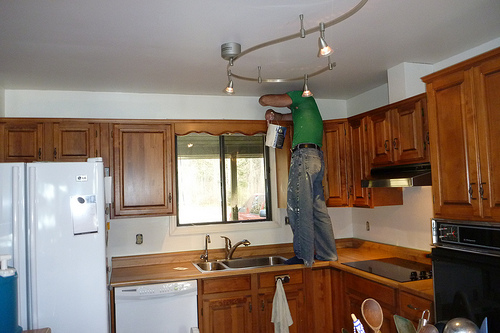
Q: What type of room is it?
A: It is a kitchen.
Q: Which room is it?
A: It is a kitchen.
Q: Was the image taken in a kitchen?
A: Yes, it was taken in a kitchen.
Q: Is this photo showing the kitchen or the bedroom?
A: It is showing the kitchen.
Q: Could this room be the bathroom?
A: No, it is the kitchen.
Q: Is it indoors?
A: Yes, it is indoors.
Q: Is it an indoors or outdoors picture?
A: It is indoors.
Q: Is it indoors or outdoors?
A: It is indoors.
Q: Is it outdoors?
A: No, it is indoors.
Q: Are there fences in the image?
A: No, there are no fences.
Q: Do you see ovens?
A: Yes, there is an oven.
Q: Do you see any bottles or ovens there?
A: Yes, there is an oven.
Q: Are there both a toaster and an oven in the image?
A: No, there is an oven but no toasters.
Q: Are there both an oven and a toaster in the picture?
A: No, there is an oven but no toasters.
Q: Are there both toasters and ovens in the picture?
A: No, there is an oven but no toasters.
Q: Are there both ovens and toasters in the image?
A: No, there is an oven but no toasters.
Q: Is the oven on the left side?
A: No, the oven is on the right of the image.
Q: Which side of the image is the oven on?
A: The oven is on the right of the image.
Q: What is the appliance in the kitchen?
A: The appliance is an oven.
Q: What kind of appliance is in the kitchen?
A: The appliance is an oven.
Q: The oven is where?
A: The oven is in the kitchen.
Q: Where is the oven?
A: The oven is in the kitchen.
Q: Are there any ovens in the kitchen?
A: Yes, there is an oven in the kitchen.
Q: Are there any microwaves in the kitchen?
A: No, there is an oven in the kitchen.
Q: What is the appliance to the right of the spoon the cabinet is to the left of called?
A: The appliance is an oven.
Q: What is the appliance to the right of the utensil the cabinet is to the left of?
A: The appliance is an oven.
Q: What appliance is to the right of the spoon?
A: The appliance is an oven.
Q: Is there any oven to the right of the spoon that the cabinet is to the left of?
A: Yes, there is an oven to the right of the spoon.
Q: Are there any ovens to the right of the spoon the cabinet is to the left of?
A: Yes, there is an oven to the right of the spoon.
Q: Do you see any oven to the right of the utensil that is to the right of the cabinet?
A: Yes, there is an oven to the right of the spoon.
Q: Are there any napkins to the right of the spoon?
A: No, there is an oven to the right of the spoon.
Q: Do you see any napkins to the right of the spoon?
A: No, there is an oven to the right of the spoon.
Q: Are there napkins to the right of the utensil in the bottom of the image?
A: No, there is an oven to the right of the spoon.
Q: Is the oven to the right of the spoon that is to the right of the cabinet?
A: Yes, the oven is to the right of the spoon.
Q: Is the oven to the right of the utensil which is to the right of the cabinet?
A: Yes, the oven is to the right of the spoon.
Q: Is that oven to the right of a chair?
A: No, the oven is to the right of the spoon.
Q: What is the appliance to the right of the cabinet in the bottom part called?
A: The appliance is an oven.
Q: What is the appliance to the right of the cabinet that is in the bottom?
A: The appliance is an oven.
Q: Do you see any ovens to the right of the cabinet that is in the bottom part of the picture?
A: Yes, there is an oven to the right of the cabinet.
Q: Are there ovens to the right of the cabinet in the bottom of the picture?
A: Yes, there is an oven to the right of the cabinet.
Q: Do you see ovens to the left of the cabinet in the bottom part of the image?
A: No, the oven is to the right of the cabinet.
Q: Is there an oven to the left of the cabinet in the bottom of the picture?
A: No, the oven is to the right of the cabinet.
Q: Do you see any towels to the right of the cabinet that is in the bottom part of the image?
A: No, there is an oven to the right of the cabinet.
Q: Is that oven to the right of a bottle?
A: No, the oven is to the right of the cabinet.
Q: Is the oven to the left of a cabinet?
A: No, the oven is to the right of a cabinet.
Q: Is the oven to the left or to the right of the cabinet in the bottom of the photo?
A: The oven is to the right of the cabinet.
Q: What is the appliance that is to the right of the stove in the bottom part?
A: The appliance is an oven.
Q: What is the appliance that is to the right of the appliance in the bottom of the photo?
A: The appliance is an oven.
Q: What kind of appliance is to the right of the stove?
A: The appliance is an oven.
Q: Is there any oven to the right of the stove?
A: Yes, there is an oven to the right of the stove.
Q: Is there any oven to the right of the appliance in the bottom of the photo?
A: Yes, there is an oven to the right of the stove.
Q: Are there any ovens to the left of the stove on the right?
A: No, the oven is to the right of the stove.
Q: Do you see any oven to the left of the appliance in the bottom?
A: No, the oven is to the right of the stove.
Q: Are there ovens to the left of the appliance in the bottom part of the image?
A: No, the oven is to the right of the stove.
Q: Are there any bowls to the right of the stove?
A: No, there is an oven to the right of the stove.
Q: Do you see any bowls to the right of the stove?
A: No, there is an oven to the right of the stove.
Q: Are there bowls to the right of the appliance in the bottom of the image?
A: No, there is an oven to the right of the stove.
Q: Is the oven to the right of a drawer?
A: No, the oven is to the right of the stove.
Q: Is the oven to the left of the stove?
A: No, the oven is to the right of the stove.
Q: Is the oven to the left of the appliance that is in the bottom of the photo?
A: No, the oven is to the right of the stove.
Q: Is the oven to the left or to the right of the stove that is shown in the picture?
A: The oven is to the right of the stove.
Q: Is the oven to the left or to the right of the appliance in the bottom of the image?
A: The oven is to the right of the stove.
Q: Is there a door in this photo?
A: Yes, there is a door.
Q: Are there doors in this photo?
A: Yes, there is a door.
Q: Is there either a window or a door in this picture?
A: Yes, there is a door.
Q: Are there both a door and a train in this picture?
A: No, there is a door but no trains.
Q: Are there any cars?
A: No, there are no cars.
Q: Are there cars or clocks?
A: No, there are no cars or clocks.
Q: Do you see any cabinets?
A: Yes, there is a cabinet.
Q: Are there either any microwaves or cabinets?
A: Yes, there is a cabinet.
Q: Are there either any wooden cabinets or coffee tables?
A: Yes, there is a wood cabinet.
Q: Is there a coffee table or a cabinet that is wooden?
A: Yes, the cabinet is wooden.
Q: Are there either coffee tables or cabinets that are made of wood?
A: Yes, the cabinet is made of wood.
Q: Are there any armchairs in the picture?
A: No, there are no armchairs.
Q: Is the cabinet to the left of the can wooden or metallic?
A: The cabinet is wooden.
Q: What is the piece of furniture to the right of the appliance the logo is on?
A: The piece of furniture is a cabinet.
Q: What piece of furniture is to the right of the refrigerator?
A: The piece of furniture is a cabinet.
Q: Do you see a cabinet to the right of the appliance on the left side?
A: Yes, there is a cabinet to the right of the freezer.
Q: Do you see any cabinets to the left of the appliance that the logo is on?
A: No, the cabinet is to the right of the refrigerator.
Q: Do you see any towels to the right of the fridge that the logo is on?
A: No, there is a cabinet to the right of the refrigerator.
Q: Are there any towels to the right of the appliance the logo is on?
A: No, there is a cabinet to the right of the refrigerator.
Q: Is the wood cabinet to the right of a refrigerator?
A: Yes, the cabinet is to the right of a refrigerator.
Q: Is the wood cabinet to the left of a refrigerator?
A: No, the cabinet is to the right of a refrigerator.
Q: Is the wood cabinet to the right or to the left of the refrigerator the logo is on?
A: The cabinet is to the right of the freezer.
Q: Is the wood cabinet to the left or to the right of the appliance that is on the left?
A: The cabinet is to the right of the freezer.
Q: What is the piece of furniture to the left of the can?
A: The piece of furniture is a cabinet.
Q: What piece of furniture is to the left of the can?
A: The piece of furniture is a cabinet.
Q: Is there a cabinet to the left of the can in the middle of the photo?
A: Yes, there is a cabinet to the left of the can.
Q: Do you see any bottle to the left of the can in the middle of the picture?
A: No, there is a cabinet to the left of the can.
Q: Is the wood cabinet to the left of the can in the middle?
A: Yes, the cabinet is to the left of the can.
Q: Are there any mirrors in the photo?
A: No, there are no mirrors.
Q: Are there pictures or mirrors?
A: No, there are no mirrors or pictures.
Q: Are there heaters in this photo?
A: No, there are no heaters.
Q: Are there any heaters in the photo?
A: No, there are no heaters.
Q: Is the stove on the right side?
A: Yes, the stove is on the right of the image.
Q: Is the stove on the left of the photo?
A: No, the stove is on the right of the image.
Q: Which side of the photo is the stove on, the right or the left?
A: The stove is on the right of the image.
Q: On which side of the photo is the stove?
A: The stove is on the right of the image.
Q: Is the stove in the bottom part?
A: Yes, the stove is in the bottom of the image.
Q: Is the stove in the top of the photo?
A: No, the stove is in the bottom of the image.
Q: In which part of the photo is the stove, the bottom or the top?
A: The stove is in the bottom of the image.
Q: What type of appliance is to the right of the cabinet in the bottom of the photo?
A: The appliance is a stove.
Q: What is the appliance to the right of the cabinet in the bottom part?
A: The appliance is a stove.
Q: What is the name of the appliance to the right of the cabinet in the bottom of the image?
A: The appliance is a stove.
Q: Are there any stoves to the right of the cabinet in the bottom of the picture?
A: Yes, there is a stove to the right of the cabinet.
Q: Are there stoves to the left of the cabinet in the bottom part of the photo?
A: No, the stove is to the right of the cabinet.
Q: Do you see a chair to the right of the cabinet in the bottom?
A: No, there is a stove to the right of the cabinet.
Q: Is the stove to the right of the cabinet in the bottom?
A: Yes, the stove is to the right of the cabinet.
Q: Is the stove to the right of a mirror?
A: No, the stove is to the right of the cabinet.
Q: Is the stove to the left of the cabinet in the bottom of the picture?
A: No, the stove is to the right of the cabinet.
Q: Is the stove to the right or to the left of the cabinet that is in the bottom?
A: The stove is to the right of the cabinet.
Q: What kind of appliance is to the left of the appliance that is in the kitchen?
A: The appliance is a stove.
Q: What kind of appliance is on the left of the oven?
A: The appliance is a stove.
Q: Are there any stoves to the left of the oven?
A: Yes, there is a stove to the left of the oven.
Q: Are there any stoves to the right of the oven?
A: No, the stove is to the left of the oven.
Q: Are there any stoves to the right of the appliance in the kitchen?
A: No, the stove is to the left of the oven.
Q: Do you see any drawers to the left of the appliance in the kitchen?
A: No, there is a stove to the left of the oven.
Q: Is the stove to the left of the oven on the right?
A: Yes, the stove is to the left of the oven.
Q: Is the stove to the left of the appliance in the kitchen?
A: Yes, the stove is to the left of the oven.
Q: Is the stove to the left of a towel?
A: No, the stove is to the left of the oven.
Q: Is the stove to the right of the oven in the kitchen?
A: No, the stove is to the left of the oven.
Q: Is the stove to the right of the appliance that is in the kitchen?
A: No, the stove is to the left of the oven.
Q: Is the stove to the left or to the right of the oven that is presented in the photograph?
A: The stove is to the left of the oven.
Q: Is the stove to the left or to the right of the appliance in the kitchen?
A: The stove is to the left of the oven.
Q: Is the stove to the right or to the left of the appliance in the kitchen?
A: The stove is to the left of the oven.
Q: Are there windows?
A: Yes, there is a window.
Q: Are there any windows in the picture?
A: Yes, there is a window.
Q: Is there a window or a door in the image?
A: Yes, there is a window.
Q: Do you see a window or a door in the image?
A: Yes, there is a window.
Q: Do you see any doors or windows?
A: Yes, there is a window.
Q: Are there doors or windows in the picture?
A: Yes, there is a window.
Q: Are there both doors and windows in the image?
A: Yes, there are both a window and a door.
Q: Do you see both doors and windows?
A: Yes, there are both a window and a door.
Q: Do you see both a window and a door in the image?
A: Yes, there are both a window and a door.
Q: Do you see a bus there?
A: No, there are no buses.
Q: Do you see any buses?
A: No, there are no buses.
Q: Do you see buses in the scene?
A: No, there are no buses.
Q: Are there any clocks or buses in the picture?
A: No, there are no buses or clocks.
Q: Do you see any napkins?
A: No, there are no napkins.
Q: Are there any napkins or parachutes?
A: No, there are no napkins or parachutes.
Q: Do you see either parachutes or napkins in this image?
A: No, there are no napkins or parachutes.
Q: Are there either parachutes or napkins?
A: No, there are no napkins or parachutes.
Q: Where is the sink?
A: The sink is in the kitchen.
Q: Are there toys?
A: No, there are no toys.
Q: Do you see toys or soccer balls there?
A: No, there are no toys or soccer balls.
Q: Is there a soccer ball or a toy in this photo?
A: No, there are no toys or soccer balls.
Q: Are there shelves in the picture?
A: No, there are no shelves.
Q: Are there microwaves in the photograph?
A: No, there are no microwaves.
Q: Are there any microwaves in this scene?
A: No, there are no microwaves.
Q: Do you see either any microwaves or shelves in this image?
A: No, there are no microwaves or shelves.